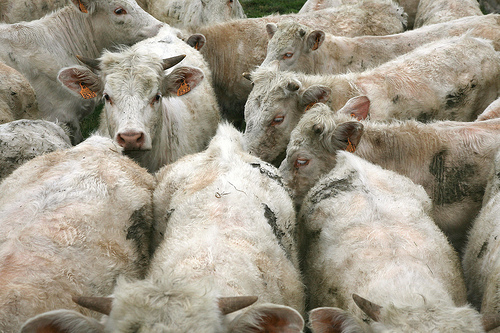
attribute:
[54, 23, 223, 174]
cow — waiting, hungry, male, watching, nervous, white, looking, meaty, out, needy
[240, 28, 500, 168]
cow — waiting, hungry, male, nervous, white, looking, watching, meaty, out, needy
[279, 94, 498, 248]
cow — waiting, hungry, male, nervous, white, looking, watching, meaty, out, needy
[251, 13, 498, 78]
cow — waiting, hungry, nervous, white, looking, watching, meaty, out, needy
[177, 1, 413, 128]
cow — waiting, hungry, male, female, white, looking, watching, meaty, out, nervous, needy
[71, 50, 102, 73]
horn — nice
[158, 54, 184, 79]
horn — nice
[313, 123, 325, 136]
horn — nice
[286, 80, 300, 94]
horn — nice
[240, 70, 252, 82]
horn — nice